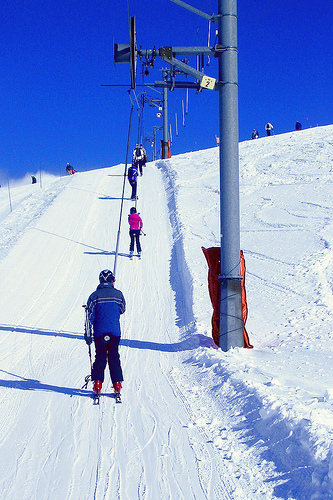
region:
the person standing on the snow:
[294, 120, 301, 130]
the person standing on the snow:
[263, 121, 272, 135]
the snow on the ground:
[0, 124, 332, 498]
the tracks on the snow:
[0, 122, 332, 494]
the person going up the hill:
[81, 268, 126, 404]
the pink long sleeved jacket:
[127, 213, 142, 230]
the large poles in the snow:
[149, 0, 245, 348]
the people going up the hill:
[84, 143, 146, 412]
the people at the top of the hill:
[29, 120, 299, 184]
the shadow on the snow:
[0, 368, 114, 396]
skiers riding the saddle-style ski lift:
[79, 136, 159, 406]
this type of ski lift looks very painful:
[80, 265, 129, 407]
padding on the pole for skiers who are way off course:
[200, 239, 257, 351]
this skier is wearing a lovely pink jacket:
[126, 209, 144, 233]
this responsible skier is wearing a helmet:
[95, 266, 116, 285]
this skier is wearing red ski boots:
[90, 377, 123, 395]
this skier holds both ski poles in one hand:
[81, 300, 95, 383]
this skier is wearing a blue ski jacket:
[83, 281, 127, 343]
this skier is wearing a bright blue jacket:
[125, 163, 140, 185]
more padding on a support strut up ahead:
[157, 136, 173, 160]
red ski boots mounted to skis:
[91, 379, 104, 396]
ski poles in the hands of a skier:
[80, 303, 94, 390]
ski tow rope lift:
[109, 1, 244, 268]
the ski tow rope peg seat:
[102, 334, 111, 344]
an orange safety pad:
[201, 246, 255, 349]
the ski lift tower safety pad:
[199, 241, 252, 351]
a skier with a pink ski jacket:
[127, 213, 143, 232]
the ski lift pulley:
[112, 14, 139, 87]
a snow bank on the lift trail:
[154, 158, 201, 352]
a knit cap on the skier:
[98, 268, 115, 283]